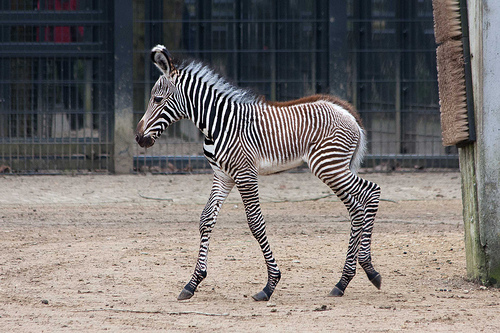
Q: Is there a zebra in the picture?
A: Yes, there is a zebra.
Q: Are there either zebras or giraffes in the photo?
A: Yes, there is a zebra.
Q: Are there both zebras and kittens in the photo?
A: No, there is a zebra but no kittens.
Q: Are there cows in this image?
A: No, there are no cows.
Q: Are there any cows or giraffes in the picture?
A: No, there are no cows or giraffes.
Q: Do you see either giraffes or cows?
A: No, there are no cows or giraffes.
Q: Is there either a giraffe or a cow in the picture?
A: No, there are no cows or giraffes.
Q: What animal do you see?
A: The animal is a zebra.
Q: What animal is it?
A: The animal is a zebra.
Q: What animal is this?
A: That is a zebra.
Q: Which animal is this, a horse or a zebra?
A: That is a zebra.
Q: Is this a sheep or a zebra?
A: This is a zebra.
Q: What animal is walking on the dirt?
A: The zebra is walking on the dirt.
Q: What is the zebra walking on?
A: The zebra is walking on the dirt.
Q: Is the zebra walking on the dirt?
A: Yes, the zebra is walking on the dirt.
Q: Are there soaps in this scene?
A: No, there are no soaps.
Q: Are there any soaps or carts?
A: No, there are no soaps or carts.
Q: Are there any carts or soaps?
A: No, there are no soaps or carts.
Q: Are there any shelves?
A: No, there are no shelves.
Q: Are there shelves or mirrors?
A: No, there are no shelves or mirrors.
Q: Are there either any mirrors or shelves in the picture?
A: No, there are no shelves or mirrors.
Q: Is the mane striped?
A: Yes, the mane is striped.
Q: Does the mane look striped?
A: Yes, the mane is striped.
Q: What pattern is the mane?
A: The mane is striped.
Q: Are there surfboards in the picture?
A: No, there are no surfboards.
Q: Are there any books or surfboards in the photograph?
A: No, there are no surfboards or books.